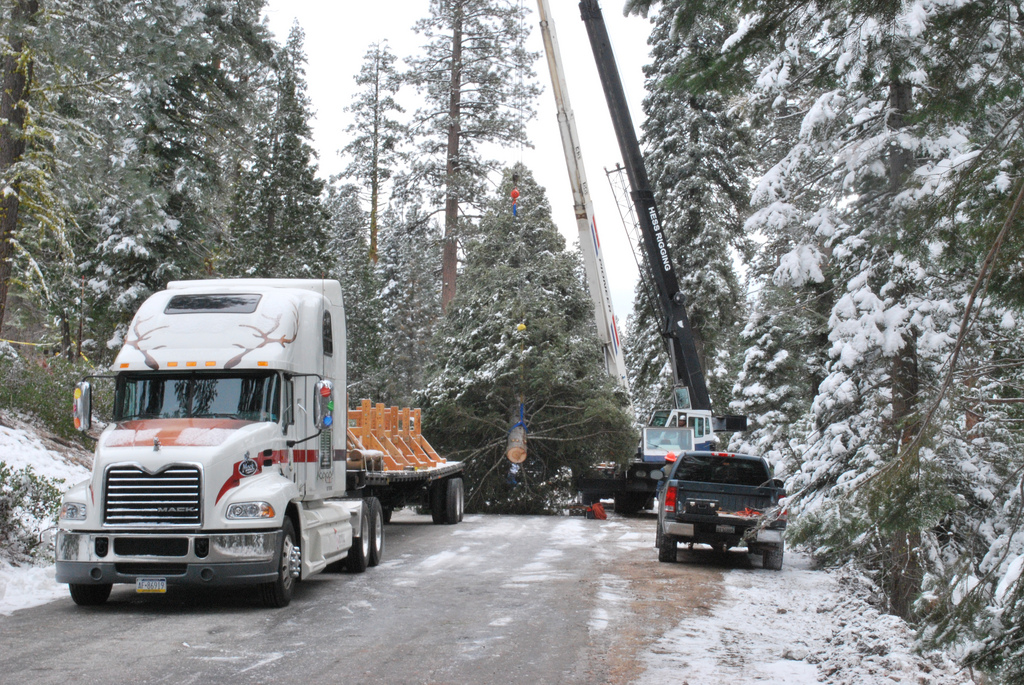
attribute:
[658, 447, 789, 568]
pick up — blue